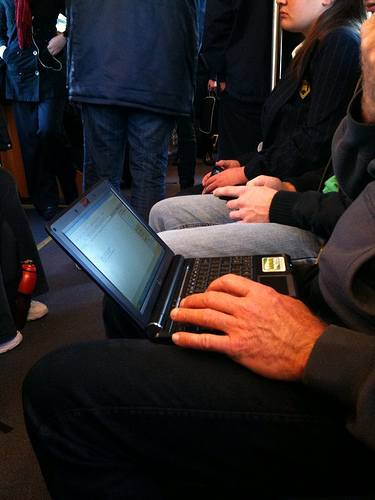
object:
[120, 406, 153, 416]
stripe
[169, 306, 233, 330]
finger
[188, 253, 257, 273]
black key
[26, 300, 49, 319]
sneaker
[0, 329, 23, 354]
sneaker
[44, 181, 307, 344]
netbook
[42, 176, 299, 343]
lap top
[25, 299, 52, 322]
shoe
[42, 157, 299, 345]
laptop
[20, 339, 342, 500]
leg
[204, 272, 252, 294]
finger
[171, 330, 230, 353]
finger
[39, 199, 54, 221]
shoe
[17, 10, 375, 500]
man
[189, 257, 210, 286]
key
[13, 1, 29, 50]
red scarf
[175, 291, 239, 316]
finger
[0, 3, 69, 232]
person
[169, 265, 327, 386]
hand